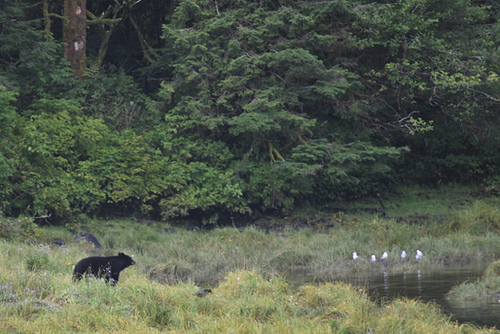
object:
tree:
[144, 0, 283, 141]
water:
[299, 261, 500, 330]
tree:
[333, 0, 415, 148]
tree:
[420, 0, 500, 188]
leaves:
[410, 99, 416, 105]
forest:
[0, 0, 498, 249]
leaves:
[78, 161, 83, 166]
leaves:
[176, 187, 179, 192]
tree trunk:
[61, 0, 88, 80]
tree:
[0, 0, 65, 114]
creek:
[281, 263, 500, 330]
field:
[0, 183, 500, 334]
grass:
[0, 185, 500, 334]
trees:
[309, 0, 376, 162]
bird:
[352, 252, 366, 261]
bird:
[371, 254, 378, 261]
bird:
[380, 251, 389, 260]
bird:
[400, 250, 407, 259]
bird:
[415, 249, 424, 261]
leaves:
[222, 103, 230, 108]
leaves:
[216, 82, 224, 86]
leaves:
[419, 127, 427, 132]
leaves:
[423, 122, 426, 127]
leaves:
[428, 119, 434, 126]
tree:
[85, 0, 189, 102]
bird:
[191, 287, 212, 298]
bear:
[71, 251, 135, 287]